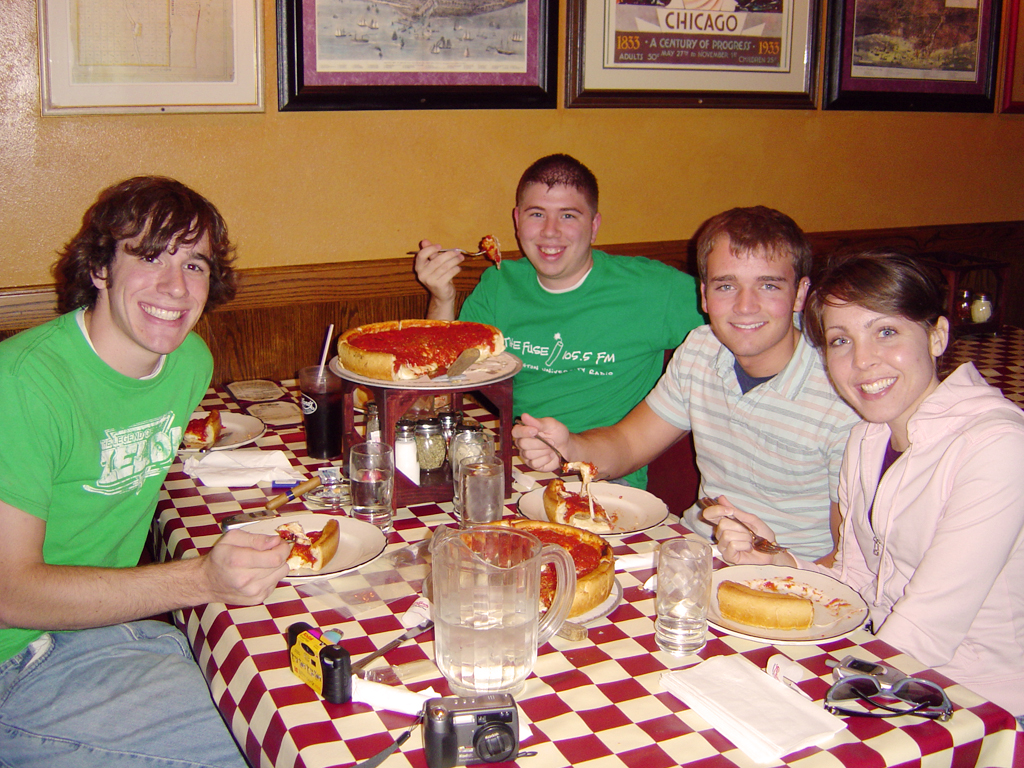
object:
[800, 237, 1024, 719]
person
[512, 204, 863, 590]
person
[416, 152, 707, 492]
person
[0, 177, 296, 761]
person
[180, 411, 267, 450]
plate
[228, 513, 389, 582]
plate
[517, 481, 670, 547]
plate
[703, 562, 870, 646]
plate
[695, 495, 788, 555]
utensil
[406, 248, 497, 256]
utensil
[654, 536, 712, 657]
vessel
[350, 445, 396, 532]
vessel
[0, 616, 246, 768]
down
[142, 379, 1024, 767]
dining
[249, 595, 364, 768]
dining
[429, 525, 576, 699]
drinking